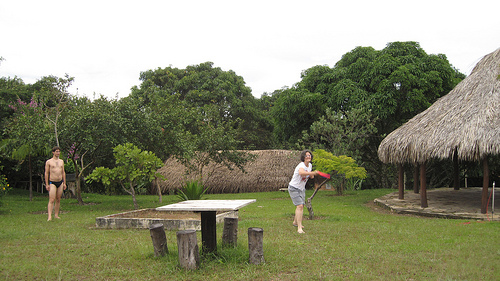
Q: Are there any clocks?
A: No, there are no clocks.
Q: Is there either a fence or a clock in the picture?
A: No, there are no clocks or fences.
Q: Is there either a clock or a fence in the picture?
A: No, there are no clocks or fences.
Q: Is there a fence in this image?
A: No, there are no fences.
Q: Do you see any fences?
A: No, there are no fences.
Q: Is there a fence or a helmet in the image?
A: No, there are no fences or helmets.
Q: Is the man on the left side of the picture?
A: Yes, the man is on the left of the image.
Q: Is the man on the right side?
A: No, the man is on the left of the image.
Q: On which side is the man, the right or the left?
A: The man is on the left of the image.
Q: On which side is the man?
A: The man is on the left of the image.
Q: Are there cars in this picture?
A: No, there are no cars.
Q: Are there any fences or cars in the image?
A: No, there are no cars or fences.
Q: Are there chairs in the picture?
A: No, there are no chairs.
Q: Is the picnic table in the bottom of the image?
A: Yes, the picnic table is in the bottom of the image.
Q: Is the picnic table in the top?
A: No, the picnic table is in the bottom of the image.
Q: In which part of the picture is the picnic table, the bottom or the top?
A: The picnic table is in the bottom of the image.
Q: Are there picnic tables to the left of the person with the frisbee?
A: Yes, there is a picnic table to the left of the person.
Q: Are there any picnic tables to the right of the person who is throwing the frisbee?
A: No, the picnic table is to the left of the person.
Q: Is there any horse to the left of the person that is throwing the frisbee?
A: No, there is a picnic table to the left of the person.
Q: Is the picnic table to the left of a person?
A: Yes, the picnic table is to the left of a person.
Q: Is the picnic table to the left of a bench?
A: No, the picnic table is to the left of a person.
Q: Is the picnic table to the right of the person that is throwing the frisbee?
A: No, the picnic table is to the left of the person.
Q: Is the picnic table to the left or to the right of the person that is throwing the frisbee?
A: The picnic table is to the left of the person.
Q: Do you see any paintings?
A: No, there are no paintings.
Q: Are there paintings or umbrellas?
A: No, there are no paintings or umbrellas.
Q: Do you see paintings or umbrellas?
A: No, there are no paintings or umbrellas.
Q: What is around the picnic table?
A: The stump is around the picnic table.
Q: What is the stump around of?
A: The stump is around the picnic table.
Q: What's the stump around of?
A: The stump is around the picnic table.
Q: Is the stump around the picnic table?
A: Yes, the stump is around the picnic table.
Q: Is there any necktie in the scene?
A: No, there are no ties.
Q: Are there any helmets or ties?
A: No, there are no ties or helmets.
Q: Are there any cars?
A: No, there are no cars.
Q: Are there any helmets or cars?
A: No, there are no cars or helmets.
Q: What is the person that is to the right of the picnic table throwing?
A: The person is throwing the frisbee.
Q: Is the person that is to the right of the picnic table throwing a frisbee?
A: Yes, the person is throwing a frisbee.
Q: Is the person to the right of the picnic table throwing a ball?
A: No, the person is throwing a frisbee.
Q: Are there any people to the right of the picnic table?
A: Yes, there is a person to the right of the picnic table.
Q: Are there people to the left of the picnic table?
A: No, the person is to the right of the picnic table.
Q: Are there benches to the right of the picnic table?
A: No, there is a person to the right of the picnic table.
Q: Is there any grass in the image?
A: Yes, there is grass.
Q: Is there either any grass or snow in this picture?
A: Yes, there is grass.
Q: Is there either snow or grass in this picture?
A: Yes, there is grass.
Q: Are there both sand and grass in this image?
A: No, there is grass but no sand.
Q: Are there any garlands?
A: No, there are no garlands.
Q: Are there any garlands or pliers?
A: No, there are no garlands or pliers.